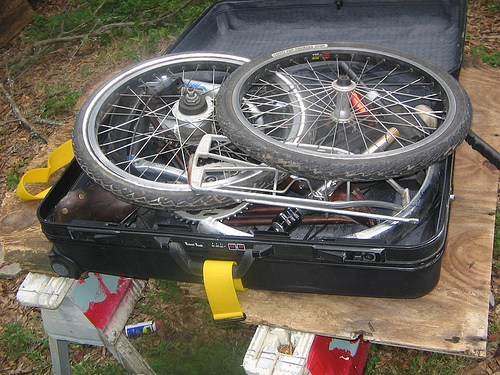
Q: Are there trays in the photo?
A: No, there are no trays.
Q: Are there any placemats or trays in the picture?
A: No, there are no trays or placemats.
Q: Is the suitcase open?
A: Yes, the suitcase is open.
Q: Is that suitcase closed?
A: No, the suitcase is open.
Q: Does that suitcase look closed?
A: No, the suitcase is open.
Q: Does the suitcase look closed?
A: No, the suitcase is open.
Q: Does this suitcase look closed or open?
A: The suitcase is open.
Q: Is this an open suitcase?
A: Yes, this is an open suitcase.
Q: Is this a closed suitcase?
A: No, this is an open suitcase.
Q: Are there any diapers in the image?
A: No, there are no diapers.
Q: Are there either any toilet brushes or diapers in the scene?
A: No, there are no diapers or toilet brushes.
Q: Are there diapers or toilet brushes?
A: No, there are no diapers or toilet brushes.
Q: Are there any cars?
A: No, there are no cars.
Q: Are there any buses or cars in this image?
A: No, there are no cars or buses.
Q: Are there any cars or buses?
A: No, there are no cars or buses.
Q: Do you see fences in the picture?
A: No, there are no fences.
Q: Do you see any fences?
A: No, there are no fences.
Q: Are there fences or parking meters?
A: No, there are no fences or parking meters.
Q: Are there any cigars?
A: No, there are no cigars.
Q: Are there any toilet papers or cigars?
A: No, there are no cigars or toilet papers.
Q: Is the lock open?
A: Yes, the lock is open.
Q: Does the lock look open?
A: Yes, the lock is open.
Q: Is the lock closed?
A: No, the lock is open.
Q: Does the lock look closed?
A: No, the lock is open.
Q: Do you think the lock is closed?
A: No, the lock is open.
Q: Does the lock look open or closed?
A: The lock is open.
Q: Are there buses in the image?
A: No, there are no buses.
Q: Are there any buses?
A: No, there are no buses.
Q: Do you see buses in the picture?
A: No, there are no buses.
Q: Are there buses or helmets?
A: No, there are no buses or helmets.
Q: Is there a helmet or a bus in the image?
A: No, there are no buses or helmets.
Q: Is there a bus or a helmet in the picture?
A: No, there are no buses or helmets.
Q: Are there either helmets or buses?
A: No, there are no buses or helmets.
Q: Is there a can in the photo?
A: Yes, there is a can.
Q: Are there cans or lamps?
A: Yes, there is a can.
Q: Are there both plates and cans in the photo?
A: No, there is a can but no plates.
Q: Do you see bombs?
A: No, there are no bombs.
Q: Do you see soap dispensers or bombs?
A: No, there are no bombs or soap dispensers.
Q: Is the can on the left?
A: Yes, the can is on the left of the image.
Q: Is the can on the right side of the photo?
A: No, the can is on the left of the image.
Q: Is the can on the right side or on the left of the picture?
A: The can is on the left of the image.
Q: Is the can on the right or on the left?
A: The can is on the left of the image.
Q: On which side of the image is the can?
A: The can is on the left of the image.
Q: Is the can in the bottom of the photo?
A: Yes, the can is in the bottom of the image.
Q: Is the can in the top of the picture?
A: No, the can is in the bottom of the image.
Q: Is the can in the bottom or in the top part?
A: The can is in the bottom of the image.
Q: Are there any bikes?
A: Yes, there is a bike.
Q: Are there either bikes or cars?
A: Yes, there is a bike.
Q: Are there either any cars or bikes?
A: Yes, there is a bike.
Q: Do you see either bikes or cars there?
A: Yes, there is a bike.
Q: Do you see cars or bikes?
A: Yes, there is a bike.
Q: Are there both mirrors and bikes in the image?
A: No, there is a bike but no mirrors.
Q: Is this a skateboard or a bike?
A: This is a bike.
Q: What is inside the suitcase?
A: The bike is inside the suitcase.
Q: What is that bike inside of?
A: The bike is inside the suitcase.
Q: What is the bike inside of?
A: The bike is inside the suitcase.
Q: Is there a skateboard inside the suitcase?
A: No, there is a bike inside the suitcase.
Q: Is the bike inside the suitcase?
A: Yes, the bike is inside the suitcase.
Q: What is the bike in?
A: The bike is in the suitcase.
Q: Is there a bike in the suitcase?
A: Yes, there is a bike in the suitcase.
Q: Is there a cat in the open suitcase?
A: No, there is a bike in the suitcase.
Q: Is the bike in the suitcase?
A: Yes, the bike is in the suitcase.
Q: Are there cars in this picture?
A: No, there are no cars.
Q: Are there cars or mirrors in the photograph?
A: No, there are no cars or mirrors.